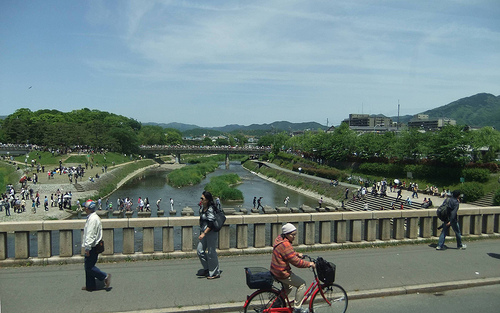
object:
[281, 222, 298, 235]
hat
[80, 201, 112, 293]
man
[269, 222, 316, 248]
boy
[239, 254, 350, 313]
bike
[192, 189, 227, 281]
woman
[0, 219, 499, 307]
bride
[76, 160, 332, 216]
water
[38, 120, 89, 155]
trees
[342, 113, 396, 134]
building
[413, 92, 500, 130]
hill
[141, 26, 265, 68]
clouds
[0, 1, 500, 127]
sky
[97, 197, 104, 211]
people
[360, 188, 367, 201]
people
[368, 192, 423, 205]
steps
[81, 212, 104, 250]
shirt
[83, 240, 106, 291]
pants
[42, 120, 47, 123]
leaves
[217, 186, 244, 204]
trees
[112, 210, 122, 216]
stones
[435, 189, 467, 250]
man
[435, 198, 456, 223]
backpack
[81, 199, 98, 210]
cap